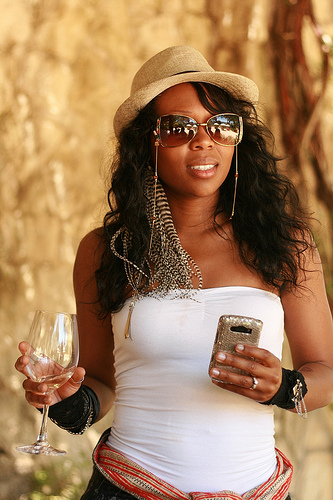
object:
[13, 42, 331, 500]
woman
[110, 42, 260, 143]
hat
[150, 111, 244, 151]
sunglasses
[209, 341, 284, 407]
left hand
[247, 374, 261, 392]
ring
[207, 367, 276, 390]
finger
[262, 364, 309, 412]
wristband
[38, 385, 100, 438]
wristband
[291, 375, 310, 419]
detail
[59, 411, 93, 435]
detail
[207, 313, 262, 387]
cell phone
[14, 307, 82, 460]
wine glass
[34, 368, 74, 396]
liquid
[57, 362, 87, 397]
right thumb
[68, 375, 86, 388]
ring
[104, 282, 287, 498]
tube top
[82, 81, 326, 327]
hair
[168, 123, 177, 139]
person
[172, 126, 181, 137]
person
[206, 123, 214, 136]
person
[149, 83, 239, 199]
face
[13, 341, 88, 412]
hand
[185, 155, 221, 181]
mouth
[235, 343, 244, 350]
fingernail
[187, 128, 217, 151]
nose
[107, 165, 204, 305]
feathers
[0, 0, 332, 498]
wall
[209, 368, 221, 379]
fingernail